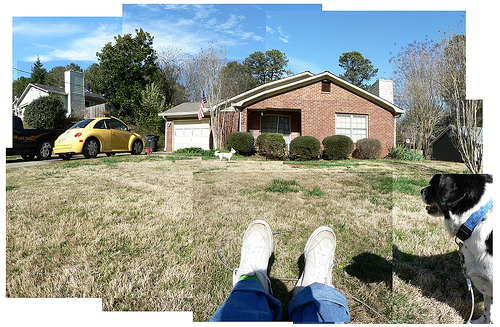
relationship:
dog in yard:
[413, 169, 493, 319] [39, 118, 392, 325]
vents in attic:
[319, 72, 331, 94] [244, 74, 394, 106]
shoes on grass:
[183, 183, 403, 300] [88, 190, 264, 318]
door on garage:
[169, 119, 215, 148] [149, 85, 224, 161]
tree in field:
[89, 39, 176, 111] [4, 157, 491, 317]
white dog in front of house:
[212, 147, 238, 162] [158, 67, 405, 161]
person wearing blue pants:
[204, 215, 352, 325] [199, 275, 353, 325]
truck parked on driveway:
[0, 116, 63, 165] [9, 157, 53, 168]